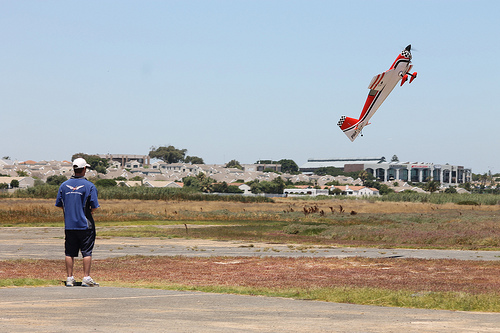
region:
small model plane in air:
[302, 49, 427, 165]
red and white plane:
[340, 44, 422, 140]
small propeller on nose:
[388, 38, 423, 62]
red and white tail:
[335, 105, 366, 159]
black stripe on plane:
[351, 56, 406, 125]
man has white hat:
[67, 161, 88, 171]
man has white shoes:
[46, 271, 101, 299]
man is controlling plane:
[48, 39, 408, 299]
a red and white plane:
[335, 42, 422, 149]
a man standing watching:
[58, 157, 109, 290]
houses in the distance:
[103, 159, 498, 196]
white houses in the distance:
[101, 157, 485, 185]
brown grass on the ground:
[184, 257, 484, 280]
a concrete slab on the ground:
[8, 285, 496, 328]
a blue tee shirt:
[53, 175, 96, 228]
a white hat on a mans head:
[69, 153, 91, 182]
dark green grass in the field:
[124, 185, 268, 205]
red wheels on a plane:
[401, 67, 418, 90]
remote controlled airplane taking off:
[337, 45, 404, 120]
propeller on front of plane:
[382, 37, 423, 62]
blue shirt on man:
[49, 160, 109, 234]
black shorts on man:
[57, 223, 99, 260]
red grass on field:
[268, 256, 421, 291]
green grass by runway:
[319, 265, 434, 306]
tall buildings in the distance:
[9, 156, 429, 201]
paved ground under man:
[38, 292, 289, 331]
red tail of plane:
[337, 110, 344, 131]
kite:
[328, 32, 426, 144]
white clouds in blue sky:
[43, 34, 75, 59]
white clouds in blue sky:
[182, 59, 209, 91]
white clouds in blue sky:
[251, 42, 302, 96]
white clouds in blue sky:
[437, 95, 475, 135]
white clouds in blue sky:
[440, 32, 480, 87]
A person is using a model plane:
[33, 25, 470, 311]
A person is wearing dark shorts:
[30, 26, 495, 312]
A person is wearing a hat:
[36, 50, 444, 320]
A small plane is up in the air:
[43, 13, 479, 304]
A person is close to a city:
[21, 33, 496, 319]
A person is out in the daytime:
[23, 16, 458, 291]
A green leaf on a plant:
[193, 183, 194, 184]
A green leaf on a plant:
[230, 189, 232, 191]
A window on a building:
[133, 162, 134, 165]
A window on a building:
[398, 168, 408, 183]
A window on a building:
[410, 168, 417, 183]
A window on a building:
[422, 169, 429, 180]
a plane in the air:
[315, 42, 475, 215]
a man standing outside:
[12, 131, 154, 288]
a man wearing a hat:
[37, 129, 86, 264]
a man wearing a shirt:
[36, 128, 143, 289]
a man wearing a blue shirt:
[58, 154, 100, 242]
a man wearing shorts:
[70, 164, 96, 236]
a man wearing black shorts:
[65, 162, 122, 269]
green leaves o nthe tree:
[172, 142, 194, 156]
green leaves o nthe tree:
[220, 154, 262, 192]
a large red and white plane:
[331, 41, 427, 144]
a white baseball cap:
[72, 155, 92, 170]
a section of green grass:
[148, 275, 498, 312]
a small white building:
[286, 185, 328, 197]